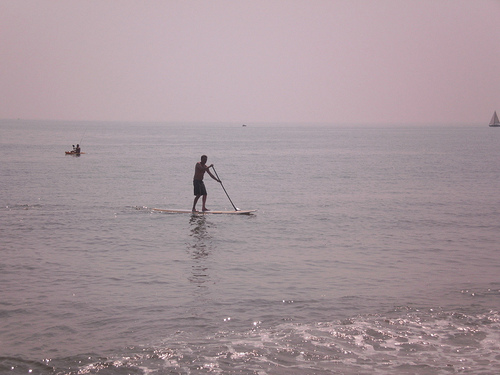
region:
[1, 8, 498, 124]
The sky is overcast.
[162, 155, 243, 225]
He is standing on his surf board.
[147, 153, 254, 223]
He is balancing.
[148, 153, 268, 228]
He is in the water.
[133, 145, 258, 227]
He has black trunks.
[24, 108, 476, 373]
He is in the ocean.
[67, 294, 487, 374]
The water is coming to the shore.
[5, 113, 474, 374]
The water is calm.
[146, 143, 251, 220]
He has a paddle.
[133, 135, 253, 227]
He is standing.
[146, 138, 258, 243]
person on paddle board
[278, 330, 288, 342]
ripple in the water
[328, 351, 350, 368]
ripple in the water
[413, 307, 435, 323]
ripple in the water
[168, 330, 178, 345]
ripple in the water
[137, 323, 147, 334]
ripple in the water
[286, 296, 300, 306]
ripple in the water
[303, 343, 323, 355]
ripple in the water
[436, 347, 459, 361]
ripple in the water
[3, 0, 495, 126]
A soothing looking sky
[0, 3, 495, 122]
the sky is a gray and fuzzy color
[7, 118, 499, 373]
wide sea water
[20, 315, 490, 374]
little splashes and waves in the sea water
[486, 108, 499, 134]
A boat in the water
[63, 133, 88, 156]
people fishing in the water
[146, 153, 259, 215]
a person standing and rowing in the water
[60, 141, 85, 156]
people sitting down in a canoe looking object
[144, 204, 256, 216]
the object is brown in color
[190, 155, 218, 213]
the person has short hair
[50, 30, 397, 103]
The sky is smoky and gray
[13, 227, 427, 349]
The water is very calm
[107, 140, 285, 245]
A man is paddle boarding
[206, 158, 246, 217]
The man is holding the paddle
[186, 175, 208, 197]
The man is wearing shorts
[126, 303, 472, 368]
A small wave washing up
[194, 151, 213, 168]
The head of the man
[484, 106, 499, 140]
A sailboat on the water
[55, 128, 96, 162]
A couple on a sailboat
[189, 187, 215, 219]
The legs of the man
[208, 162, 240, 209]
A paddle i the man's hands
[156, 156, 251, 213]
A man paddling on a board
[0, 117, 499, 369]
Calm water below the sky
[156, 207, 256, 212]
A board in the water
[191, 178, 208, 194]
The man is wearing shorts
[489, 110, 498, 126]
A sailboat in the distance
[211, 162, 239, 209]
The paddle is touching the water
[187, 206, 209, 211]
The man is not wearing shoes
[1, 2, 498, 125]
The sky above the water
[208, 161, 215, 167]
The right hand of the man